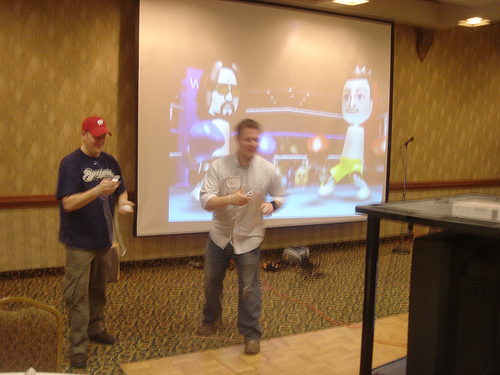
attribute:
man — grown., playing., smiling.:
[198, 120, 288, 356]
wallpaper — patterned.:
[440, 32, 500, 179]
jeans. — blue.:
[202, 233, 264, 328]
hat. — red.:
[80, 116, 114, 137]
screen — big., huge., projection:
[136, 2, 400, 231]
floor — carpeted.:
[32, 249, 344, 335]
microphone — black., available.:
[403, 135, 415, 151]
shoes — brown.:
[67, 330, 116, 370]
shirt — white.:
[199, 152, 285, 251]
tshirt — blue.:
[52, 151, 124, 251]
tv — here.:
[406, 230, 499, 374]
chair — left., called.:
[2, 298, 66, 374]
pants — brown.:
[62, 247, 111, 348]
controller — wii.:
[243, 190, 257, 197]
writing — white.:
[81, 168, 113, 182]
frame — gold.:
[14, 296, 56, 310]